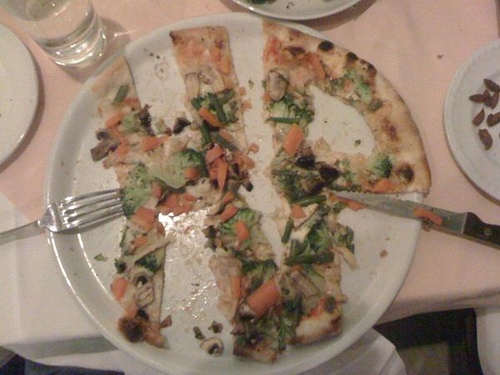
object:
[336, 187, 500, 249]
knife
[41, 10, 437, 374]
plate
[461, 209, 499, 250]
handle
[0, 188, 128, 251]
fork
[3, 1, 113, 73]
glass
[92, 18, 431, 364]
dish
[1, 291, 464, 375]
edge of table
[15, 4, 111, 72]
water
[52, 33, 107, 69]
light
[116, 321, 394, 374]
edge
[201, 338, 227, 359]
crumb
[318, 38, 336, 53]
spot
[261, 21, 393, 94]
crust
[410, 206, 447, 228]
food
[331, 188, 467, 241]
blade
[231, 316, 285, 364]
piece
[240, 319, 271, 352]
meat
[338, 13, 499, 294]
table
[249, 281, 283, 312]
carrot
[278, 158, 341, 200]
broccoli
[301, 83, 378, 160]
hole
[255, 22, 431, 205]
slice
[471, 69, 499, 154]
nuts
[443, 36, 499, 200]
plate